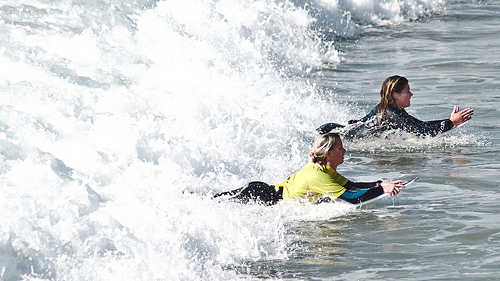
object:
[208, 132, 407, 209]
woman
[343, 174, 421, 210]
surfboard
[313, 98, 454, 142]
wet suit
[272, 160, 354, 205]
t-shirt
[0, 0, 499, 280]
water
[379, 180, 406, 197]
hand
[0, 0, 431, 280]
white froth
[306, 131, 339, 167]
hair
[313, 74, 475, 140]
girl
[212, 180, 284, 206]
pants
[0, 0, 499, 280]
wave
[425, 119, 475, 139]
board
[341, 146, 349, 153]
nose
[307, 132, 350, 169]
head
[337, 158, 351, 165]
chin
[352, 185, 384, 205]
forearm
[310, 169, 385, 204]
arm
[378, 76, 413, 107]
head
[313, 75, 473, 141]
woman